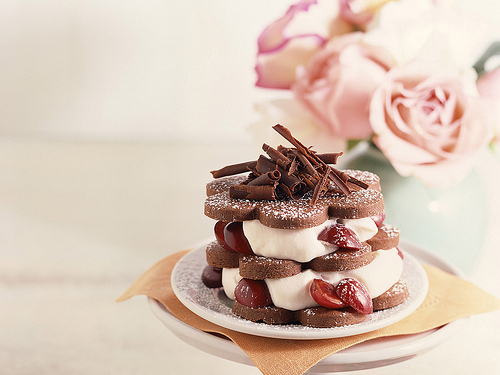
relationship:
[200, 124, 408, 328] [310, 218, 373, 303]
cake with strawberries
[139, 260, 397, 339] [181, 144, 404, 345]
plate with dessert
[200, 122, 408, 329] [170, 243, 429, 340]
dessert piled onto plate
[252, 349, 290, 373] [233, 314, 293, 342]
napkin under plate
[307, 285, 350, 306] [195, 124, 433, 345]
strawberries on cake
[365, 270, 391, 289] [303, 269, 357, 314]
cream and strawberries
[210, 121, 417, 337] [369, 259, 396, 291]
cake with cream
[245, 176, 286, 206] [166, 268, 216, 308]
chocolate on plate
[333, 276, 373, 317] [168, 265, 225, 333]
cherry on plate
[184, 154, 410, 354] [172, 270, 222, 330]
desert on plate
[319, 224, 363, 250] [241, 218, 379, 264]
cherry in whipped cream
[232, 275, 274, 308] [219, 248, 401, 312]
cherry in cream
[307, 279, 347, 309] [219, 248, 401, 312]
cherry in cream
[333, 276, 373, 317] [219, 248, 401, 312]
cherry in cream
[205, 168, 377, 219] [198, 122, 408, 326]
powdered sugar dusted on desert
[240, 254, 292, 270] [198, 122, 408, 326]
powdered sugar dusted on desert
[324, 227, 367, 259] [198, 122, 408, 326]
powdered sugar dusted on desert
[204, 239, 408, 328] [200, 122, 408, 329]
layer on dessert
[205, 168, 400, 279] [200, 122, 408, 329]
layer on dessert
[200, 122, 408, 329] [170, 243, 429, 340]
dessert on plate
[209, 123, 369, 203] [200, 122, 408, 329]
chocolate shavings on top of dessert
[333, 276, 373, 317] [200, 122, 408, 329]
cherry on dessert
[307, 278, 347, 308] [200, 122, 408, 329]
cherry on dessert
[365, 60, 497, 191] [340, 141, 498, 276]
rose in vase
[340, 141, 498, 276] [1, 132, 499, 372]
vase on table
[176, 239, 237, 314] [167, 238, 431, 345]
powdered sugar dusted on plate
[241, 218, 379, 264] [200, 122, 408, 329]
whipped cream in dessert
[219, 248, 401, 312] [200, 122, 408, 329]
cream in dessert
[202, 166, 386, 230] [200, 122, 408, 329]
pastry on dessert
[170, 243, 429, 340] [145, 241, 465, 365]
plate on top of plate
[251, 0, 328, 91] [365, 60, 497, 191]
edge on rose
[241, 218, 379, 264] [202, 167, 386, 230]
whipped cream placed underneath pastry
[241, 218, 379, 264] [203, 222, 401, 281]
whipped cream topping cookie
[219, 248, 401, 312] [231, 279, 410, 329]
cream topping cookie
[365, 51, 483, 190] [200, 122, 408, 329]
rose blooming behind dessert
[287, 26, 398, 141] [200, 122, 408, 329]
rose blooming behind dessert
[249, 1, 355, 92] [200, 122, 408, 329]
rose blooming behind dessert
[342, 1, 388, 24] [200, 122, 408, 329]
rose blooming behind dessert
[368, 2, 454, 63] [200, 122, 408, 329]
rose blooming behind dessert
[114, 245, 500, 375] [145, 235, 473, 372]
napkin lying on top of plate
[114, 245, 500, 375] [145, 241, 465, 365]
napkin lying on top of plate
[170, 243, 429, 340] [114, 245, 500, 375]
plate sitting on top of napkin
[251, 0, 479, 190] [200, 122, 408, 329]
flower bunch standing behind dessert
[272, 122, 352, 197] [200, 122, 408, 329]
shaving topping dessert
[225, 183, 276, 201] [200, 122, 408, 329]
shaving topping dessert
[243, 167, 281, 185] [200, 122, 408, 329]
shaving topping dessert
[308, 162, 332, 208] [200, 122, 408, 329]
shaving topping dessert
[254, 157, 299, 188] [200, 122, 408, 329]
shaving topping dessert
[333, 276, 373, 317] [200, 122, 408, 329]
cherry placed on dessert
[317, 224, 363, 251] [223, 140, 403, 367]
cherry on desert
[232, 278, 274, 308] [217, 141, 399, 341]
cherry on desert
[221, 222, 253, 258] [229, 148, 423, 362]
cherry on desert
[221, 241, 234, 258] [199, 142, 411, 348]
cherry on desert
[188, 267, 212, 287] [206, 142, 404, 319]
cherry on desert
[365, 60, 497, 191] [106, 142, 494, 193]
rose in background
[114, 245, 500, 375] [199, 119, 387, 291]
napkin under desert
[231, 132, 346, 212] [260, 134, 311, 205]
pile of chocolate shavings